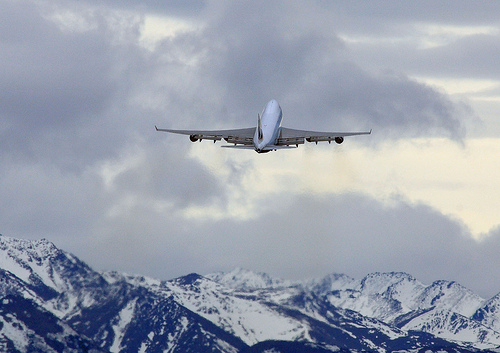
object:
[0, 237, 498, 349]
mountain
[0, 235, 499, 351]
snow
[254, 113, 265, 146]
tail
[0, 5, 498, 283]
cloud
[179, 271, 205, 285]
mountain peak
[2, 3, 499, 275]
sky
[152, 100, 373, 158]
plane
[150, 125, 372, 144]
wings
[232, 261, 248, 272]
point